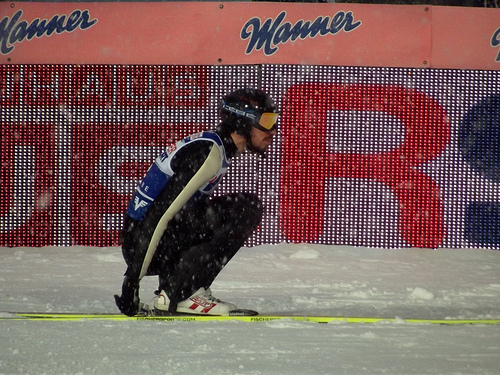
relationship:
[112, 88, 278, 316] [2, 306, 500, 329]
athlete kneeling on skis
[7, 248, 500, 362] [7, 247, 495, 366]
snow on ground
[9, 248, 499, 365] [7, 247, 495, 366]
ice on ground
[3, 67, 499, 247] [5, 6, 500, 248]
sign in background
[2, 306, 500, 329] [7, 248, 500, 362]
skis in snow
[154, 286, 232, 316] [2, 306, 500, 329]
shoes on skis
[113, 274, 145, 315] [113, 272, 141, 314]
gloves on hands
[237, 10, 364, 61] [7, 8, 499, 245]
manner written on wall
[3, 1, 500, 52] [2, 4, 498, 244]
logos on back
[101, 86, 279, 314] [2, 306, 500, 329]
man on skis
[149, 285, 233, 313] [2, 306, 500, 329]
shoes in skis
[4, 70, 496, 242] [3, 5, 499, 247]
led lights on sign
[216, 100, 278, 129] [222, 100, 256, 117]
goggles have strap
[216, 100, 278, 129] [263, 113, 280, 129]
goggles have tint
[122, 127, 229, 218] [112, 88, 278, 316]
vest on athlete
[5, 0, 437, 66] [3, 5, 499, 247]
rivets in sign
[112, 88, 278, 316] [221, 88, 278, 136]
athlete has helmet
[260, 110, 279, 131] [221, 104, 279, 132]
lens on goggles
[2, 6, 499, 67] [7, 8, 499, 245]
banner on wall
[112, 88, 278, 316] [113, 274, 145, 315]
athlete has gloves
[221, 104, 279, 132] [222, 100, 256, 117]
goggles have strap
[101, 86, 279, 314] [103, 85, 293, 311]
man in position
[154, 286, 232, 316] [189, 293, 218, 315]
shoes with accents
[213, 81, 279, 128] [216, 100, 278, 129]
helmet with goggles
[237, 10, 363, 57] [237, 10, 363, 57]
manner in manner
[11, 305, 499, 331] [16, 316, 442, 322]
object with text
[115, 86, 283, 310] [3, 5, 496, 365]
athlete playing sport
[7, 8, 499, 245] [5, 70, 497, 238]
wall with letters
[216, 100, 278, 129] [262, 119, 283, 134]
goggles around eyes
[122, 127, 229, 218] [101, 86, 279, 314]
vest on man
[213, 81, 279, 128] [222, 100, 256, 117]
helmet has strap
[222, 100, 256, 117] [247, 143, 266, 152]
strap attached under chin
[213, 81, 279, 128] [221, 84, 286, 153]
helmet on head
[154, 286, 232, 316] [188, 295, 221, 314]
shoes with stripes